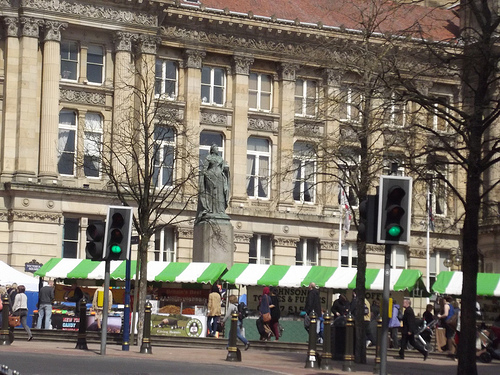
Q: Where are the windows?
A: Building.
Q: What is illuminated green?
A: Traffic control signal.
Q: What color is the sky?
A: Pink.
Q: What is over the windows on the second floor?
A: Curtains.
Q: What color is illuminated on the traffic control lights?
A: Green.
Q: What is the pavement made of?
A: Concrete.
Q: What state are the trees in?
A: Bare.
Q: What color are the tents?
A: Green and white.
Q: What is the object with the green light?
A: A traffic light.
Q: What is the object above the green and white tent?
A: A statue.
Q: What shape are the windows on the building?
A: A rectangle.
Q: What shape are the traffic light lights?
A: Circles.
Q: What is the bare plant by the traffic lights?
A: A tree.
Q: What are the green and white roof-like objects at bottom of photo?
A: Awnings.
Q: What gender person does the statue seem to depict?
A: Woman ruler.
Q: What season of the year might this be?
A: Autumn.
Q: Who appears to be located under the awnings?
A: Street vendors.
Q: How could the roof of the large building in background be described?
A: Red.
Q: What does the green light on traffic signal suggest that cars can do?
A: Go.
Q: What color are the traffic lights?
A: Green.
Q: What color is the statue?
A: Grey.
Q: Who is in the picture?
A: People walking on the street.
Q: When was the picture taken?
A: While the light was green.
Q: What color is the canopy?
A: Green and white.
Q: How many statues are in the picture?
A: One.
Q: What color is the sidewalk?
A: Red.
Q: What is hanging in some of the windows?
A: Curtains.